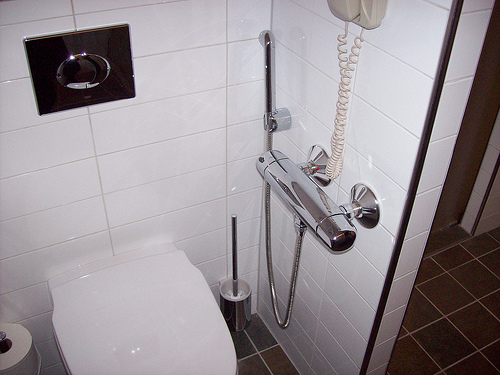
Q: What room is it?
A: It is a bathroom.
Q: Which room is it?
A: It is a bathroom.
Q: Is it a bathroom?
A: Yes, it is a bathroom.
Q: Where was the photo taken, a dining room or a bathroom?
A: It was taken at a bathroom.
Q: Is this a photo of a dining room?
A: No, the picture is showing a bathroom.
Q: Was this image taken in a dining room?
A: No, the picture was taken in a bathroom.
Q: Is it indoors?
A: Yes, it is indoors.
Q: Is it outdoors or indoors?
A: It is indoors.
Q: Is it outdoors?
A: No, it is indoors.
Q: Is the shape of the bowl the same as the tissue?
A: Yes, both the bowl and the tissue are round.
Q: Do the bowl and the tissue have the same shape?
A: Yes, both the bowl and the tissue are round.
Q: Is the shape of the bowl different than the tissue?
A: No, both the bowl and the tissue are round.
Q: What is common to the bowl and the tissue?
A: The shape, both the bowl and the tissue are round.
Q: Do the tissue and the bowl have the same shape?
A: Yes, both the tissue and the bowl are round.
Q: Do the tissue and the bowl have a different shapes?
A: No, both the tissue and the bowl are round.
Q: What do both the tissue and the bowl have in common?
A: The shape, both the tissue and the bowl are round.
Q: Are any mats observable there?
A: No, there are no mats.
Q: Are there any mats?
A: No, there are no mats.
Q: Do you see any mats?
A: No, there are no mats.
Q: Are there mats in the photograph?
A: No, there are no mats.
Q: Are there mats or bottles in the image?
A: No, there are no mats or bottles.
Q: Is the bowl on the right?
A: No, the bowl is on the left of the image.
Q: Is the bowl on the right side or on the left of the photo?
A: The bowl is on the left of the image.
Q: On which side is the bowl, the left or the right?
A: The bowl is on the left of the image.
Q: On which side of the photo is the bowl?
A: The bowl is on the left of the image.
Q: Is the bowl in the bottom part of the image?
A: Yes, the bowl is in the bottom of the image.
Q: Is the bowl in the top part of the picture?
A: No, the bowl is in the bottom of the image.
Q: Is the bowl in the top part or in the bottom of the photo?
A: The bowl is in the bottom of the image.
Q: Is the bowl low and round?
A: Yes, the bowl is low and round.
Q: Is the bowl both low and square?
A: No, the bowl is low but round.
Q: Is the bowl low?
A: Yes, the bowl is low.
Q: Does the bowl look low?
A: Yes, the bowl is low.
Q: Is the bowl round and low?
A: Yes, the bowl is round and low.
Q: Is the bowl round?
A: Yes, the bowl is round.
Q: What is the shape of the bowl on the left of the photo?
A: The bowl is round.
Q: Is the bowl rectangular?
A: No, the bowl is round.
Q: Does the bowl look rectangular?
A: No, the bowl is round.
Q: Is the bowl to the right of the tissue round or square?
A: The bowl is round.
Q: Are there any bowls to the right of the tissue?
A: Yes, there is a bowl to the right of the tissue.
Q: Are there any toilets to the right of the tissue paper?
A: No, there is a bowl to the right of the tissue paper.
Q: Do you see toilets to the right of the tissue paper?
A: No, there is a bowl to the right of the tissue paper.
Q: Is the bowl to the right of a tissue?
A: Yes, the bowl is to the right of a tissue.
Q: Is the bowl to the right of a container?
A: No, the bowl is to the right of a tissue.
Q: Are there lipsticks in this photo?
A: No, there are no lipsticks.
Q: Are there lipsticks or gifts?
A: No, there are no lipsticks or gifts.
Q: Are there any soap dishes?
A: No, there are no soap dishes.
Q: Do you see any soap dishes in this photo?
A: No, there are no soap dishes.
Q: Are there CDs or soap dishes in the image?
A: No, there are no soap dishes or cds.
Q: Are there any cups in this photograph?
A: Yes, there is a cup.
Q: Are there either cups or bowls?
A: Yes, there is a cup.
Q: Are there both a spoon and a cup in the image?
A: No, there is a cup but no spoons.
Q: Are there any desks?
A: No, there are no desks.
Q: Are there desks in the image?
A: No, there are no desks.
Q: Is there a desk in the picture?
A: No, there are no desks.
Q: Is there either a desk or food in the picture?
A: No, there are no desks or food.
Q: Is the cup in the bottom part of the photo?
A: Yes, the cup is in the bottom of the image.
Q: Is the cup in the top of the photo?
A: No, the cup is in the bottom of the image.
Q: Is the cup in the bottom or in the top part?
A: The cup is in the bottom of the image.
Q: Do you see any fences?
A: No, there are no fences.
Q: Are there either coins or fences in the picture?
A: No, there are no fences or coins.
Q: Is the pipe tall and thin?
A: Yes, the pipe is tall and thin.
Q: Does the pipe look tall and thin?
A: Yes, the pipe is tall and thin.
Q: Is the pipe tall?
A: Yes, the pipe is tall.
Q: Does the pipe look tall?
A: Yes, the pipe is tall.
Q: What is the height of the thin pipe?
A: The pipe is tall.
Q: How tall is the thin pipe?
A: The pipe is tall.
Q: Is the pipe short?
A: No, the pipe is tall.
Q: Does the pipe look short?
A: No, the pipe is tall.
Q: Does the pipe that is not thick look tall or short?
A: The pipe is tall.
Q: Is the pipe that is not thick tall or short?
A: The pipe is tall.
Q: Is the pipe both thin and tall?
A: Yes, the pipe is thin and tall.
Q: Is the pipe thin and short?
A: No, the pipe is thin but tall.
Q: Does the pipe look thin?
A: Yes, the pipe is thin.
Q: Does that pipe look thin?
A: Yes, the pipe is thin.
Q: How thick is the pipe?
A: The pipe is thin.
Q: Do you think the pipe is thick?
A: No, the pipe is thin.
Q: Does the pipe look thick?
A: No, the pipe is thin.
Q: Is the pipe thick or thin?
A: The pipe is thin.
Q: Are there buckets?
A: No, there are no buckets.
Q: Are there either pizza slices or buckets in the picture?
A: No, there are no buckets or pizza slices.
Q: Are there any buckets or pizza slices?
A: No, there are no buckets or pizza slices.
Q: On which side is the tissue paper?
A: The tissue paper is on the left of the image.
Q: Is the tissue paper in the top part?
A: No, the tissue paper is in the bottom of the image.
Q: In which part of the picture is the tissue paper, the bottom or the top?
A: The tissue paper is in the bottom of the image.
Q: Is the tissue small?
A: Yes, the tissue is small.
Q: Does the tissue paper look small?
A: Yes, the tissue paper is small.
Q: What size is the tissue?
A: The tissue is small.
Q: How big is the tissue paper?
A: The tissue paper is small.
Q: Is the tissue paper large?
A: No, the tissue paper is small.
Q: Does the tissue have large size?
A: No, the tissue is small.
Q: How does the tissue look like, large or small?
A: The tissue is small.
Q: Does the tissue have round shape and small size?
A: Yes, the tissue is round and small.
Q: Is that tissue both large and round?
A: No, the tissue is round but small.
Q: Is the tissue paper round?
A: Yes, the tissue paper is round.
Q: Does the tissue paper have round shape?
A: Yes, the tissue paper is round.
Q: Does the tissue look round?
A: Yes, the tissue is round.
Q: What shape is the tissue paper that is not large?
A: The tissue is round.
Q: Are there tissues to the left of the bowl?
A: Yes, there is a tissue to the left of the bowl.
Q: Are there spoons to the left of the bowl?
A: No, there is a tissue to the left of the bowl.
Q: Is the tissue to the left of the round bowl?
A: Yes, the tissue is to the left of the bowl.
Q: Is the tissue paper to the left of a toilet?
A: No, the tissue paper is to the left of the bowl.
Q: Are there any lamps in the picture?
A: No, there are no lamps.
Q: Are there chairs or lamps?
A: No, there are no lamps or chairs.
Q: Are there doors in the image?
A: Yes, there is a door.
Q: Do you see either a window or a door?
A: Yes, there is a door.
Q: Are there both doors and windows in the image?
A: No, there is a door but no windows.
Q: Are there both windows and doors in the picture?
A: No, there is a door but no windows.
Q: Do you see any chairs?
A: No, there are no chairs.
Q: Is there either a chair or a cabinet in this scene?
A: No, there are no chairs or cabinets.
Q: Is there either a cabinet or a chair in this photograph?
A: No, there are no chairs or cabinets.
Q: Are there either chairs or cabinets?
A: No, there are no chairs or cabinets.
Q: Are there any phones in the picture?
A: Yes, there is a phone.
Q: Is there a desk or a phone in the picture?
A: Yes, there is a phone.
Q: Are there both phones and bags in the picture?
A: No, there is a phone but no bags.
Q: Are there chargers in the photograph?
A: No, there are no chargers.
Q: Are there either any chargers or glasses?
A: No, there are no chargers or glasses.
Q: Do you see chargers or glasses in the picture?
A: No, there are no chargers or glasses.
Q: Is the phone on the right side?
A: Yes, the phone is on the right of the image.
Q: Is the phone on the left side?
A: No, the phone is on the right of the image.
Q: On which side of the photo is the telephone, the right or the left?
A: The telephone is on the right of the image.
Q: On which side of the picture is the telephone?
A: The telephone is on the right of the image.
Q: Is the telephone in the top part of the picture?
A: Yes, the telephone is in the top of the image.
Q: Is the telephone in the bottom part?
A: No, the telephone is in the top of the image.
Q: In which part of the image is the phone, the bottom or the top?
A: The phone is in the top of the image.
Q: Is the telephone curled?
A: Yes, the telephone is curled.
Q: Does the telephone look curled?
A: Yes, the telephone is curled.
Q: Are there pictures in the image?
A: No, there are no pictures.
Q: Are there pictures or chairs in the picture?
A: No, there are no pictures or chairs.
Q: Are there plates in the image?
A: Yes, there is a plate.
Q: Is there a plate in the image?
A: Yes, there is a plate.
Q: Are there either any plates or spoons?
A: Yes, there is a plate.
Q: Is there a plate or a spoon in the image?
A: Yes, there is a plate.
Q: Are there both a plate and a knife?
A: No, there is a plate but no knives.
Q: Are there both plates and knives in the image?
A: No, there is a plate but no knives.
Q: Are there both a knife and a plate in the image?
A: No, there is a plate but no knives.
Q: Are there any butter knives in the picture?
A: No, there are no butter knives.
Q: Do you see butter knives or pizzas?
A: No, there are no butter knives or pizzas.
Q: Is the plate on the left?
A: Yes, the plate is on the left of the image.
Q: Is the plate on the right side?
A: No, the plate is on the left of the image.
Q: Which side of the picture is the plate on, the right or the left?
A: The plate is on the left of the image.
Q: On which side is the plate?
A: The plate is on the left of the image.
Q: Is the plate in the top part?
A: Yes, the plate is in the top of the image.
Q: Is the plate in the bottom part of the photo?
A: No, the plate is in the top of the image.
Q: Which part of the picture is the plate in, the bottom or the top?
A: The plate is in the top of the image.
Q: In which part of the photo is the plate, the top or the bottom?
A: The plate is in the top of the image.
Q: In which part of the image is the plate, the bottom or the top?
A: The plate is in the top of the image.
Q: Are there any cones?
A: No, there are no cones.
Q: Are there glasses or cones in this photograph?
A: No, there are no cones or glasses.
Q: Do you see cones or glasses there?
A: No, there are no cones or glasses.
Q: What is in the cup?
A: The brush is in the cup.